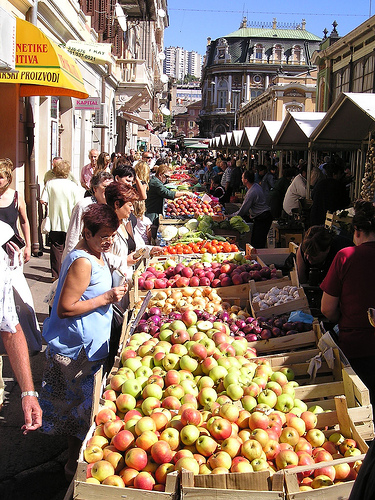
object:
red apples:
[137, 260, 277, 291]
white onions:
[252, 285, 300, 310]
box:
[248, 270, 310, 318]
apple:
[84, 309, 362, 493]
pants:
[250, 209, 272, 249]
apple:
[198, 387, 218, 406]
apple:
[181, 267, 194, 278]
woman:
[0, 157, 32, 272]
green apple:
[123, 357, 143, 372]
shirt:
[319, 240, 375, 347]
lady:
[39, 159, 77, 282]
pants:
[49, 230, 66, 280]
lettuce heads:
[169, 231, 226, 246]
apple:
[134, 366, 153, 379]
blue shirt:
[42, 249, 114, 362]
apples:
[138, 263, 277, 290]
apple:
[121, 377, 142, 399]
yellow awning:
[0, 11, 90, 99]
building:
[0, 0, 90, 256]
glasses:
[91, 231, 117, 241]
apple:
[257, 389, 277, 409]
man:
[37, 203, 130, 477]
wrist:
[20, 390, 39, 398]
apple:
[274, 393, 295, 414]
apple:
[209, 418, 232, 440]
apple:
[275, 448, 299, 470]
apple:
[113, 429, 135, 451]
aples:
[147, 252, 254, 271]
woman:
[296, 224, 356, 307]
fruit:
[84, 252, 362, 492]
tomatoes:
[222, 242, 231, 253]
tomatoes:
[210, 245, 217, 254]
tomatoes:
[192, 244, 200, 253]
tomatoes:
[183, 248, 189, 254]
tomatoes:
[171, 248, 177, 254]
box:
[127, 241, 245, 266]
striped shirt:
[220, 166, 232, 187]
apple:
[201, 252, 213, 263]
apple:
[162, 353, 180, 372]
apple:
[199, 277, 210, 286]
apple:
[159, 427, 181, 451]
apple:
[142, 383, 163, 401]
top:
[0, 190, 26, 250]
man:
[225, 170, 272, 250]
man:
[219, 160, 232, 202]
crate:
[106, 347, 348, 386]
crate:
[132, 257, 311, 318]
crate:
[157, 224, 239, 245]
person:
[319, 201, 375, 422]